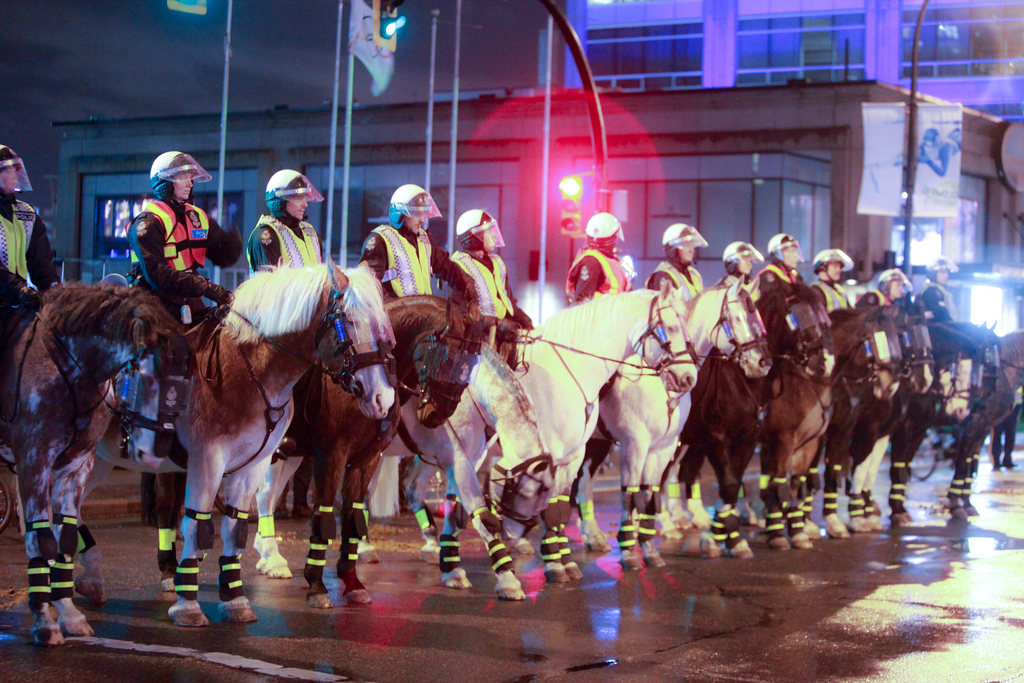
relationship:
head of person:
[582, 210, 632, 247] [571, 204, 632, 293]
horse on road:
[601, 290, 762, 541] [660, 512, 913, 670]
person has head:
[658, 212, 711, 277] [642, 210, 720, 340]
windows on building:
[558, 13, 922, 115] [66, 46, 991, 431]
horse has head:
[828, 298, 909, 517] [847, 291, 906, 410]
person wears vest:
[114, 138, 236, 290] [132, 205, 213, 275]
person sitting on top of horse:
[0, 144, 89, 581] [0, 269, 305, 656]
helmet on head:
[140, 137, 221, 187] [149, 137, 204, 207]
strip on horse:
[19, 550, 95, 617] [0, 269, 305, 656]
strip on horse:
[45, 559, 85, 605] [6, 284, 309, 641]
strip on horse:
[51, 508, 82, 532] [3, 266, 189, 658]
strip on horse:
[49, 551, 78, 571] [3, 266, 189, 658]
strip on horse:
[176, 558, 200, 578] [49, 255, 421, 632]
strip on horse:
[172, 577, 201, 601] [49, 255, 421, 632]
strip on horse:
[300, 536, 333, 554] [144, 266, 479, 610]